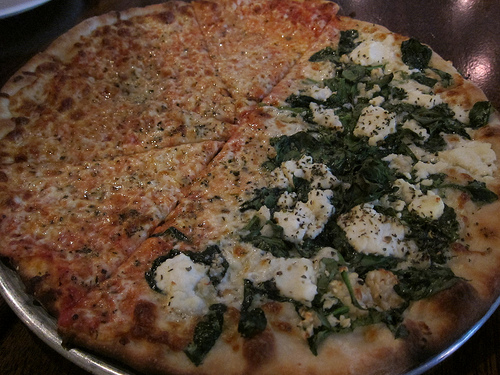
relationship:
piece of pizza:
[281, 132, 487, 299] [239, 15, 280, 69]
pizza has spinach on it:
[239, 15, 280, 69] [350, 63, 365, 102]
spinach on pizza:
[346, 56, 359, 62] [239, 15, 280, 69]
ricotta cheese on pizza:
[230, 251, 313, 298] [239, 15, 280, 69]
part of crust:
[51, 45, 68, 64] [67, 34, 92, 45]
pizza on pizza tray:
[239, 15, 280, 69] [9, 306, 56, 342]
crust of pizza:
[67, 34, 92, 45] [239, 15, 280, 69]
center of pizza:
[203, 92, 274, 161] [239, 15, 280, 69]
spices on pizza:
[361, 101, 387, 130] [239, 15, 280, 69]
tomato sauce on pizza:
[37, 258, 93, 306] [239, 15, 280, 69]